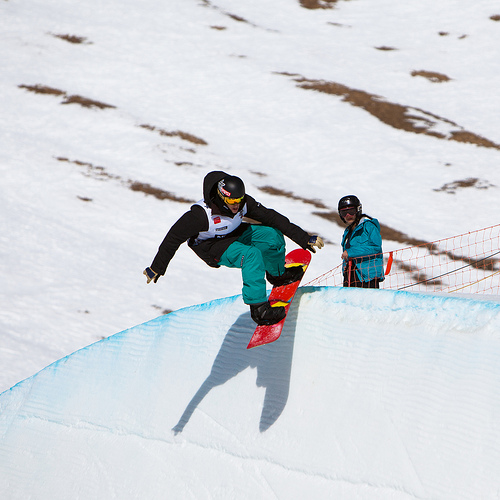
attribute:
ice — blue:
[36, 325, 152, 372]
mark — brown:
[75, 122, 155, 188]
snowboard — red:
[255, 261, 320, 345]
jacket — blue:
[352, 238, 379, 267]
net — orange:
[305, 254, 497, 300]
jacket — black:
[173, 222, 237, 248]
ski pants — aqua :
[232, 215, 289, 313]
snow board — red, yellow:
[246, 245, 308, 362]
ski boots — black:
[257, 268, 299, 324]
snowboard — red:
[223, 240, 316, 367]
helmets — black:
[218, 172, 370, 217]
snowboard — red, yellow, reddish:
[247, 248, 314, 351]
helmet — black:
[335, 192, 365, 222]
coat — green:
[338, 213, 388, 288]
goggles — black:
[337, 204, 363, 220]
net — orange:
[302, 220, 483, 301]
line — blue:
[4, 285, 485, 404]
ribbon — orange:
[375, 247, 406, 279]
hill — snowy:
[3, 283, 475, 498]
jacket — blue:
[340, 214, 383, 286]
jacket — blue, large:
[334, 215, 384, 285]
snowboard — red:
[242, 245, 314, 348]